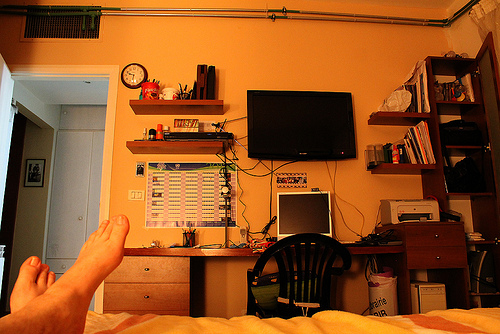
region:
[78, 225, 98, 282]
part of a pair of feet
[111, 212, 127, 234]
toe of a foot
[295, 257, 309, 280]
back of a chair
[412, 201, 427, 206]
part of a printer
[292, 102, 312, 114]
part of a screen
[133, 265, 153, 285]
part of a drawer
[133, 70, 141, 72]
part of a clock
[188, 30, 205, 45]
section of a wall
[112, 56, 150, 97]
black and white clock on wall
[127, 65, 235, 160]
wooden shelving on wall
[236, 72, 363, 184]
flat screen TV on wall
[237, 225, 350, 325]
black chair under desk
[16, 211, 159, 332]
person's bare feet on bed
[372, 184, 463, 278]
computer printer on desk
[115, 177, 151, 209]
white light switch on wall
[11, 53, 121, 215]
white trim on doorway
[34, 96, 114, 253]
white doors outside room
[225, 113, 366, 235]
electronics wires on wall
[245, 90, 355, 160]
black TV mounted on wall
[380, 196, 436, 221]
white printer above drawers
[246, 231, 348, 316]
black chair in front of desk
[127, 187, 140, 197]
white lightswitch on wall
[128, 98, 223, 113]
brown floating shelf on wall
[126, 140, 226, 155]
brown floating shelf on wall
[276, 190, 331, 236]
square computer monitor on desk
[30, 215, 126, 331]
left foot is bare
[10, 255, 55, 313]
right foot is bare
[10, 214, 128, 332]
feet are crossed on bed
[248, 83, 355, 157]
flat screen television monitor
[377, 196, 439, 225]
white computer printer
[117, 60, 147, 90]
white and brown clock on wall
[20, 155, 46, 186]
picture hanging on wall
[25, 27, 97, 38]
grey metal air vent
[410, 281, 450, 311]
white computer tower on ground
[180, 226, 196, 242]
metal container with pens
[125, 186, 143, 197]
white light switch panel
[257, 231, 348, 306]
back of black desk chair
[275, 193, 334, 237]
silver computer monitor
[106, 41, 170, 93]
white clock on the wall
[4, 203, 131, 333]
feet of the person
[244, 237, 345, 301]
black chair in room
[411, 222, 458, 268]
two wooden things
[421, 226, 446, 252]
knob on the drawer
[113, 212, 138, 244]
big toe of person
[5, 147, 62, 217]
picture on the wall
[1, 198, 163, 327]
crossed feet on the bed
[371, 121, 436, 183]
stack of things on shelf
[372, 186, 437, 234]
printer on top of drawer